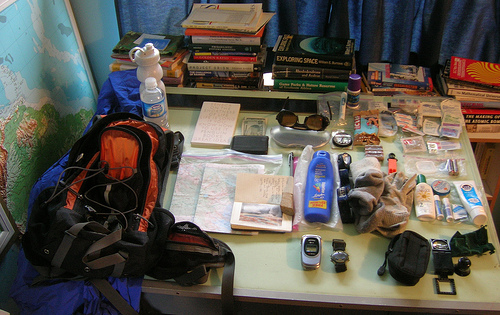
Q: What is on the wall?
A: A map.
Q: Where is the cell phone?
A: On the table.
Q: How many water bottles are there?
A: Two.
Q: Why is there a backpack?
A: To store all of the materials.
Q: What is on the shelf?
A: Books.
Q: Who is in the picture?
A: Nobody.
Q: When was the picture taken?
A: Daytime.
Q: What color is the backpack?
A: Orange.